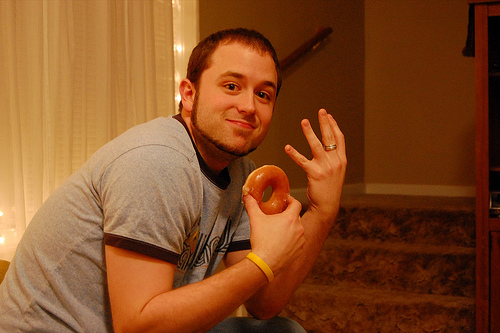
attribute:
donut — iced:
[241, 164, 290, 212]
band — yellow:
[246, 251, 276, 284]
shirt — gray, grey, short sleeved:
[0, 114, 256, 332]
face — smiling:
[209, 46, 275, 150]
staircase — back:
[249, 189, 475, 332]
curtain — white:
[0, 0, 175, 264]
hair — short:
[177, 27, 282, 111]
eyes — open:
[221, 80, 272, 102]